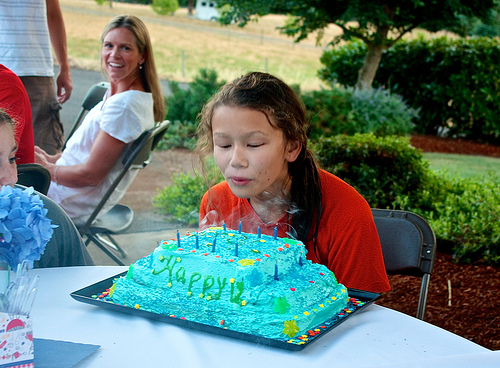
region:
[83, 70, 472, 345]
girl blowing out candles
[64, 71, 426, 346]
girl looking at birthday cake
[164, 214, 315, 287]
candles on birthday cake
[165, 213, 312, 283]
blue candles are wax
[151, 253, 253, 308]
word Happy written on cake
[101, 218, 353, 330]
cake iceing is blue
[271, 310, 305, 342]
yellow flower on birthday cake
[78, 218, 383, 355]
birthday cake on blue tray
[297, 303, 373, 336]
confetti on edge of tray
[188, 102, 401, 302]
girl wearing red shirt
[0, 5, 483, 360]
people celebrating a birthday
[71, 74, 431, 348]
girl in red shirt blowing out candles of birthday cake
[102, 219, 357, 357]
cake decorated with blue icing and star sprinkles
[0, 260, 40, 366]
plastic utensils in a multicolored box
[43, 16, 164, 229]
woman sitting in green folding chair and smiling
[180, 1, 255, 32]
white vehicle in the background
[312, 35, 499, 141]
green shrubbery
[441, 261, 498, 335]
red mulch on the ground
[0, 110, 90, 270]
person in green shirt sitting at table behind blue flowers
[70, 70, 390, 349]
young girl with brown hair sitting behind large blue cake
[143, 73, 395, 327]
a girl blwing out birthday candles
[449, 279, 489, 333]
brown mulch of the garden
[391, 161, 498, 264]
green plants growing in the garden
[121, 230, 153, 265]
grey concrete of the patio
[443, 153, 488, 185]
green grass of the yard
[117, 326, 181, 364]
white surface of the table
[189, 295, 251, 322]
blue icing of the cake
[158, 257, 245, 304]
green letters on the blue cake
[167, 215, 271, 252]
several blue candles on top of the cake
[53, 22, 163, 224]
a woman wearing a white shirt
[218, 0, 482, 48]
leaves on tree branches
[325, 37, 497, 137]
green leaves on hedge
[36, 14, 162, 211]
woman with turned head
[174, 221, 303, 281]
blue candles on cake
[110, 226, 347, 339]
cake with blue frosting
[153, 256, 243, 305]
green writing on cake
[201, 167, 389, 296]
short sleeved orange shirt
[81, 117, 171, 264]
side of folding chair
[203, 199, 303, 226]
smoke from blown out candles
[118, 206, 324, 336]
blue 3 layer cake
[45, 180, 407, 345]
three layer birthday cake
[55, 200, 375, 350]
blue birthday cake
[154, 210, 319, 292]
blue candles on blue cake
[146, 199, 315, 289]
candles blown out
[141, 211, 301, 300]
12 candles on birthday cake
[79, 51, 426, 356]
girl with 12th birthday cake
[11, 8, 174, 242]
woman sitting watching the birthday girl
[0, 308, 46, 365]
present on table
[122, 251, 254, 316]
happy written in green frosting